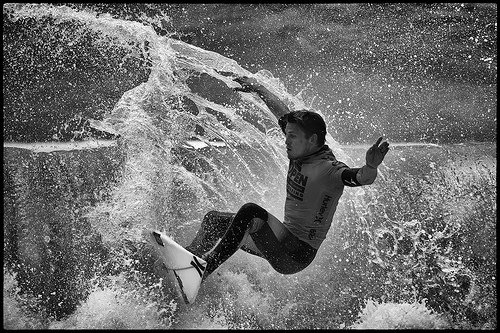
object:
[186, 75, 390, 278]
man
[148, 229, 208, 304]
board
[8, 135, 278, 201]
waves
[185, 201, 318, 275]
pants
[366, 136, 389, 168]
hand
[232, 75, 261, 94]
hand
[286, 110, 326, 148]
hair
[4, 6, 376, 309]
water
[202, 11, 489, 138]
sky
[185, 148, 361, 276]
wetsuit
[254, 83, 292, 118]
arm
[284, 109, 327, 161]
head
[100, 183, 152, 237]
splash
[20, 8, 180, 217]
wall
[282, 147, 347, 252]
shirt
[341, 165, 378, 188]
arm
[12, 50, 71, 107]
spray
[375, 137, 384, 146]
finger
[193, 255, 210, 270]
stripe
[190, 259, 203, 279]
stripe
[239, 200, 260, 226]
knee